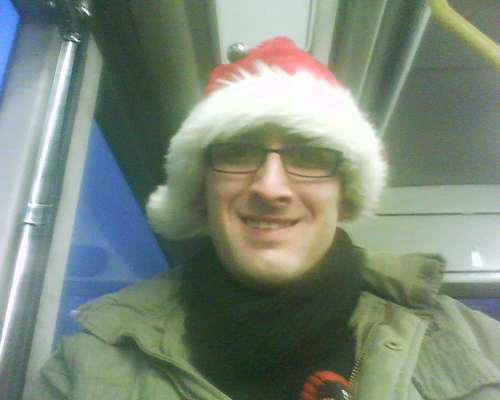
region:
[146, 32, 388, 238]
red and white santa hat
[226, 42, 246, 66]
bell on santa hat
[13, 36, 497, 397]
man wearing green coat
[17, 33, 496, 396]
man wearing santa hat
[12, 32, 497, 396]
man wearing black scarf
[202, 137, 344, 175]
glasses with black trim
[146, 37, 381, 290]
man wearing glasses with black rim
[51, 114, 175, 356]
window behind man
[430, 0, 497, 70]
handle bar is yellow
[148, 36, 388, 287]
santa hat is red with white brim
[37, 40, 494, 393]
a person in a red and white hat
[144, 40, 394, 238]
a red and white hat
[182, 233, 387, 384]
a black scarf around neck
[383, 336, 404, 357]
a button on a jacket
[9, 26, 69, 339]
a silver metal pipe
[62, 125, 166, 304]
a glass window behind the man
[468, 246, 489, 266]
a reflection on the wall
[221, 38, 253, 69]
a silver bell on the cap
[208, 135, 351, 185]
black rim glasses on a face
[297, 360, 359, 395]
a red and black sweater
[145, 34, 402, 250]
man is wearing a santa hat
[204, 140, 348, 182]
man is wearing glasses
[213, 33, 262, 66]
bell at the top of santa hat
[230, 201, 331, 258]
man is smiling towards the camera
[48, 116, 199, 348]
wall is blue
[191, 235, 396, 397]
man is wearing a black shirt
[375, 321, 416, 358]
button on the jacket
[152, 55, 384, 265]
bottom of hat is fuzzy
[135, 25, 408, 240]
santa hat is red and white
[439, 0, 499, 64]
pole is yellow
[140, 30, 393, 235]
A red and white christmas hat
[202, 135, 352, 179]
a pair of black rim, reading glasses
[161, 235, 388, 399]
a black scarf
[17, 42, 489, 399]
a man wearing a khaki jack and smiling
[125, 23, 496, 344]
a man on a metro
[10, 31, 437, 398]
a man on a bus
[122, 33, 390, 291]
a man wearing a santa hat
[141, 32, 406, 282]
a man wearing a christmas hat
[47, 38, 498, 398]
a young man smiling on the bus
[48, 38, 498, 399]
a young man smiling on the metro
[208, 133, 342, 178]
black framed eye glasses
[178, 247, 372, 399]
black scarf around man's neck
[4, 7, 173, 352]
windows on the left side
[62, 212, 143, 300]
reflection on window beside man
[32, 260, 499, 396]
green coat of man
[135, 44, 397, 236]
santa hat with white ball and trim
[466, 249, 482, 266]
light glare on the wall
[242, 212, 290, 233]
teeth of the man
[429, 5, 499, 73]
yellow bar on right side